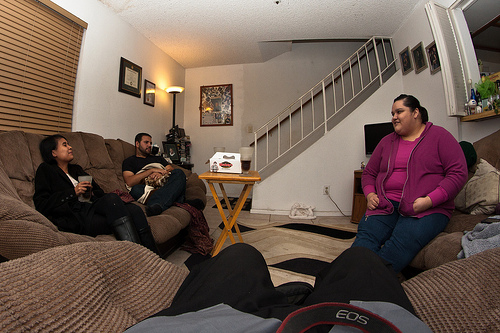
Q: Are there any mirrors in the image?
A: No, there are no mirrors.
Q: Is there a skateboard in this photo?
A: No, there are no skateboards.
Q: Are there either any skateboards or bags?
A: No, there are no skateboards or bags.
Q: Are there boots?
A: Yes, there are boots.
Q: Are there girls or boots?
A: Yes, there are boots.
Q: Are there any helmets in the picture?
A: No, there are no helmets.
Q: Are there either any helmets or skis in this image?
A: No, there are no helmets or skis.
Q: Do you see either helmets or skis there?
A: No, there are no helmets or skis.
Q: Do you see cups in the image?
A: Yes, there is a cup.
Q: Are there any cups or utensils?
A: Yes, there is a cup.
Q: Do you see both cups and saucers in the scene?
A: No, there is a cup but no saucers.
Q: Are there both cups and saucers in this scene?
A: No, there is a cup but no saucers.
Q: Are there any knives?
A: No, there are no knives.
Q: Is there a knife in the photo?
A: No, there are no knives.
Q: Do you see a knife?
A: No, there are no knives.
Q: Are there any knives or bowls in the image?
A: No, there are no knives or bowls.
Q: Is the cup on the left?
A: Yes, the cup is on the left of the image.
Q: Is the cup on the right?
A: No, the cup is on the left of the image.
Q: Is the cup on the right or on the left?
A: The cup is on the left of the image.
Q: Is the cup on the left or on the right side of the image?
A: The cup is on the left of the image.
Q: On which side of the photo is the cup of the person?
A: The cup is on the left of the image.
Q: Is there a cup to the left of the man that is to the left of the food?
A: Yes, there is a cup to the left of the man.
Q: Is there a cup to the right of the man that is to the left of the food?
A: No, the cup is to the left of the man.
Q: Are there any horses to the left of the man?
A: No, there is a cup to the left of the man.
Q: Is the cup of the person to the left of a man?
A: Yes, the cup is to the left of a man.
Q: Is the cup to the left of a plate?
A: No, the cup is to the left of a man.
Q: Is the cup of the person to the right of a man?
A: No, the cup is to the left of a man.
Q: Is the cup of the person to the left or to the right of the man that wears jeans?
A: The cup is to the left of the man.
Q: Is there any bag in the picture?
A: No, there are no bags.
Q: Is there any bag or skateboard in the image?
A: No, there are no bags or skateboards.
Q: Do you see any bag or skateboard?
A: No, there are no bags or skateboards.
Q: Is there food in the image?
A: Yes, there is food.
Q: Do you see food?
A: Yes, there is food.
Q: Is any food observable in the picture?
A: Yes, there is food.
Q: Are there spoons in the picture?
A: No, there are no spoons.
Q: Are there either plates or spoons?
A: No, there are no spoons or plates.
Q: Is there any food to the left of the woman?
A: Yes, there is food to the left of the woman.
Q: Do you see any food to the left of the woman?
A: Yes, there is food to the left of the woman.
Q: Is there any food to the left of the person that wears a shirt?
A: Yes, there is food to the left of the woman.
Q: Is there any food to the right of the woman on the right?
A: No, the food is to the left of the woman.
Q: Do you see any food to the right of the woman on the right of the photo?
A: No, the food is to the left of the woman.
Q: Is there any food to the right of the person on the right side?
A: No, the food is to the left of the woman.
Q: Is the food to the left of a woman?
A: Yes, the food is to the left of a woman.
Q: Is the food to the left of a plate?
A: No, the food is to the left of a woman.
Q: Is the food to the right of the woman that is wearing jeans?
A: No, the food is to the left of the woman.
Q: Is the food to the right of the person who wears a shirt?
A: No, the food is to the left of the woman.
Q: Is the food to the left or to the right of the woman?
A: The food is to the left of the woman.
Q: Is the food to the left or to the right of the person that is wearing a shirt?
A: The food is to the left of the woman.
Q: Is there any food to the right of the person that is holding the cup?
A: Yes, there is food to the right of the person.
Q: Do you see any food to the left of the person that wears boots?
A: No, the food is to the right of the person.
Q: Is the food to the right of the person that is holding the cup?
A: Yes, the food is to the right of the person.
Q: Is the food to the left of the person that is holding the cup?
A: No, the food is to the right of the person.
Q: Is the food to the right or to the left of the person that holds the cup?
A: The food is to the right of the person.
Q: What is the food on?
A: The food is on the table.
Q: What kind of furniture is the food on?
A: The food is on the table.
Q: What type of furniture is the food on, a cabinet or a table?
A: The food is on a table.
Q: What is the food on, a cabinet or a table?
A: The food is on a table.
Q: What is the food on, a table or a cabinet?
A: The food is on a table.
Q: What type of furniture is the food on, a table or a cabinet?
A: The food is on a table.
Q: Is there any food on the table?
A: Yes, there is food on the table.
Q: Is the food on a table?
A: Yes, the food is on a table.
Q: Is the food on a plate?
A: No, the food is on a table.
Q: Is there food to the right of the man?
A: Yes, there is food to the right of the man.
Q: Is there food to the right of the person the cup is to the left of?
A: Yes, there is food to the right of the man.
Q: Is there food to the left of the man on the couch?
A: No, the food is to the right of the man.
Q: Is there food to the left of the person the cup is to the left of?
A: No, the food is to the right of the man.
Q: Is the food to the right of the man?
A: Yes, the food is to the right of the man.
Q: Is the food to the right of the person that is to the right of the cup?
A: Yes, the food is to the right of the man.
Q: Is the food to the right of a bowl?
A: No, the food is to the right of the man.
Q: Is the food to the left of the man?
A: No, the food is to the right of the man.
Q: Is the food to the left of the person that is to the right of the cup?
A: No, the food is to the right of the man.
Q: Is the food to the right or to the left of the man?
A: The food is to the right of the man.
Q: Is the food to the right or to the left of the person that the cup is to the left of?
A: The food is to the right of the man.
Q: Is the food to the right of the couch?
A: Yes, the food is to the right of the couch.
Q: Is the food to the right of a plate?
A: No, the food is to the right of the couch.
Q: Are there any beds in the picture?
A: No, there are no beds.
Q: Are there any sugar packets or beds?
A: No, there are no beds or sugar packets.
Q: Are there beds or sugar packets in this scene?
A: No, there are no beds or sugar packets.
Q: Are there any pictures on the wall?
A: Yes, there is a picture on the wall.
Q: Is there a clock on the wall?
A: No, there is a picture on the wall.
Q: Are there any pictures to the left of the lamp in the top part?
A: Yes, there is a picture to the left of the lamp.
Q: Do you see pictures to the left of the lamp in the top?
A: Yes, there is a picture to the left of the lamp.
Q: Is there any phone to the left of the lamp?
A: No, there is a picture to the left of the lamp.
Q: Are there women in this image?
A: Yes, there is a woman.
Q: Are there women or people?
A: Yes, there is a woman.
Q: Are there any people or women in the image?
A: Yes, there is a woman.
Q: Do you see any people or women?
A: Yes, there is a woman.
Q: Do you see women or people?
A: Yes, there is a woman.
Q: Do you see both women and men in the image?
A: Yes, there are both a woman and a man.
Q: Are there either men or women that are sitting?
A: Yes, the woman is sitting.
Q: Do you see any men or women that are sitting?
A: Yes, the woman is sitting.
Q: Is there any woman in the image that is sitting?
A: Yes, there is a woman that is sitting.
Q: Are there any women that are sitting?
A: Yes, there is a woman that is sitting.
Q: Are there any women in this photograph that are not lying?
A: Yes, there is a woman that is sitting.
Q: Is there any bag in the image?
A: No, there are no bags.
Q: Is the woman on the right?
A: Yes, the woman is on the right of the image.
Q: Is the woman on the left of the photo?
A: No, the woman is on the right of the image.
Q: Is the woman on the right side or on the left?
A: The woman is on the right of the image.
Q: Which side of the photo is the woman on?
A: The woman is on the right of the image.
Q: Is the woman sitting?
A: Yes, the woman is sitting.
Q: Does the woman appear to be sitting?
A: Yes, the woman is sitting.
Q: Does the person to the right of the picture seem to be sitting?
A: Yes, the woman is sitting.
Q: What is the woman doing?
A: The woman is sitting.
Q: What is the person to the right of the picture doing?
A: The woman is sitting.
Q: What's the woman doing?
A: The woman is sitting.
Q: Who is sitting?
A: The woman is sitting.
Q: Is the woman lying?
A: No, the woman is sitting.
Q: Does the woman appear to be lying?
A: No, the woman is sitting.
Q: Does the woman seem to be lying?
A: No, the woman is sitting.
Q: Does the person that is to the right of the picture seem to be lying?
A: No, the woman is sitting.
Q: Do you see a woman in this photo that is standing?
A: No, there is a woman but she is sitting.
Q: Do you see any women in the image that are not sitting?
A: No, there is a woman but she is sitting.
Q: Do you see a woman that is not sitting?
A: No, there is a woman but she is sitting.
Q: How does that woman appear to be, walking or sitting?
A: The woman is sitting.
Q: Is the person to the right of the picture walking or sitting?
A: The woman is sitting.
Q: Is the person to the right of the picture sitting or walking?
A: The woman is sitting.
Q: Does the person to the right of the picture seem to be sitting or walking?
A: The woman is sitting.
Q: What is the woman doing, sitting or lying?
A: The woman is sitting.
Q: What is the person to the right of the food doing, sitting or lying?
A: The woman is sitting.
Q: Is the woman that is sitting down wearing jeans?
A: Yes, the woman is wearing jeans.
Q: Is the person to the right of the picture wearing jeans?
A: Yes, the woman is wearing jeans.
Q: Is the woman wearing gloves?
A: No, the woman is wearing jeans.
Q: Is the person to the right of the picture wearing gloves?
A: No, the woman is wearing jeans.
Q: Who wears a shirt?
A: The woman wears a shirt.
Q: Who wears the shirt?
A: The woman wears a shirt.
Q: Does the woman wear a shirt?
A: Yes, the woman wears a shirt.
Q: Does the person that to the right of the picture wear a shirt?
A: Yes, the woman wears a shirt.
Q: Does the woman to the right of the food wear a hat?
A: No, the woman wears a shirt.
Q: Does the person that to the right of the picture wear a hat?
A: No, the woman wears a shirt.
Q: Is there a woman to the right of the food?
A: Yes, there is a woman to the right of the food.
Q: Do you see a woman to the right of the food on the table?
A: Yes, there is a woman to the right of the food.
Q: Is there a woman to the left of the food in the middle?
A: No, the woman is to the right of the food.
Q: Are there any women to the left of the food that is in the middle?
A: No, the woman is to the right of the food.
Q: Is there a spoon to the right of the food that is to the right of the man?
A: No, there is a woman to the right of the food.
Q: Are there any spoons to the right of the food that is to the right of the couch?
A: No, there is a woman to the right of the food.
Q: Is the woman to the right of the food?
A: Yes, the woman is to the right of the food.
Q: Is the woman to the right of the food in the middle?
A: Yes, the woman is to the right of the food.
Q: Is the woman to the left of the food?
A: No, the woman is to the right of the food.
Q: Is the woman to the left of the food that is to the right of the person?
A: No, the woman is to the right of the food.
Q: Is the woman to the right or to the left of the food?
A: The woman is to the right of the food.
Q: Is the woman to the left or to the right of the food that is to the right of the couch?
A: The woman is to the right of the food.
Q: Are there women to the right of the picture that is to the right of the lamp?
A: Yes, there is a woman to the right of the picture.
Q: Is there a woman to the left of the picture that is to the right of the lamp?
A: No, the woman is to the right of the picture.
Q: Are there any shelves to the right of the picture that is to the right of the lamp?
A: No, there is a woman to the right of the picture.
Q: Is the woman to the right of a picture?
A: Yes, the woman is to the right of a picture.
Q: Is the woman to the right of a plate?
A: No, the woman is to the right of a picture.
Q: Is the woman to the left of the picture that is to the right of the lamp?
A: No, the woman is to the right of the picture.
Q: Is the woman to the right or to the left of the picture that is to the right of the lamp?
A: The woman is to the right of the picture.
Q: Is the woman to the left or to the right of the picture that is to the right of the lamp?
A: The woman is to the right of the picture.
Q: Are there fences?
A: No, there are no fences.